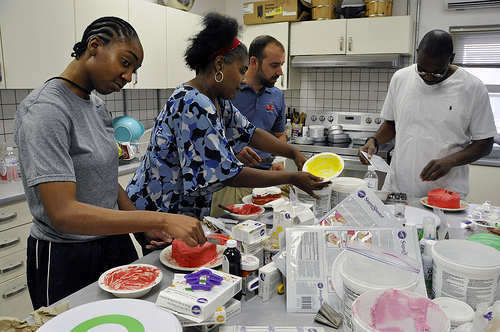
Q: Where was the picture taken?
A: It was taken at the kitchen.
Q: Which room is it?
A: It is a kitchen.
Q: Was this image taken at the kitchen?
A: Yes, it was taken in the kitchen.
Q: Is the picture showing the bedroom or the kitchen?
A: It is showing the kitchen.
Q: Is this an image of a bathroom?
A: No, the picture is showing a kitchen.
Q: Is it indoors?
A: Yes, it is indoors.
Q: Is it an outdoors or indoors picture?
A: It is indoors.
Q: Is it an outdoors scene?
A: No, it is indoors.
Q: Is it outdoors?
A: No, it is indoors.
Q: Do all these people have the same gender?
A: No, they are both male and female.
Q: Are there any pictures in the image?
A: No, there are no pictures.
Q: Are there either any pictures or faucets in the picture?
A: No, there are no pictures or faucets.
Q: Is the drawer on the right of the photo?
A: No, the drawer is on the left of the image.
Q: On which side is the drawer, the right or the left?
A: The drawer is on the left of the image.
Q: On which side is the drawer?
A: The drawer is on the left of the image.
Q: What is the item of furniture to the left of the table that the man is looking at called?
A: The piece of furniture is a drawer.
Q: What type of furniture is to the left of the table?
A: The piece of furniture is a drawer.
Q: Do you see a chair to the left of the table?
A: No, there is a drawer to the left of the table.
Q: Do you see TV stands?
A: No, there are no TV stands.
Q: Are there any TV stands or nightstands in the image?
A: No, there are no TV stands or nightstands.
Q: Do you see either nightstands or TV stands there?
A: No, there are no TV stands or nightstands.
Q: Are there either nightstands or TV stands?
A: No, there are no TV stands or nightstands.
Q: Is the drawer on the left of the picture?
A: Yes, the drawer is on the left of the image.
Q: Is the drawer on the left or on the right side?
A: The drawer is on the left of the image.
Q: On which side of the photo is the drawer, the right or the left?
A: The drawer is on the left of the image.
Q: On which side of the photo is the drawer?
A: The drawer is on the left of the image.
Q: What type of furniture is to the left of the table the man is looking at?
A: The piece of furniture is a drawer.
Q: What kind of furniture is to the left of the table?
A: The piece of furniture is a drawer.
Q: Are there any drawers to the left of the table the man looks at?
A: Yes, there is a drawer to the left of the table.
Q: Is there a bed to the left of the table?
A: No, there is a drawer to the left of the table.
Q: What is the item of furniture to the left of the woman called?
A: The piece of furniture is a drawer.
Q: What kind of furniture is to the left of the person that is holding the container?
A: The piece of furniture is a drawer.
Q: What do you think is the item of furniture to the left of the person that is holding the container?
A: The piece of furniture is a drawer.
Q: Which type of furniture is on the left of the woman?
A: The piece of furniture is a drawer.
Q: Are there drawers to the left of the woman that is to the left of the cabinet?
A: Yes, there is a drawer to the left of the woman.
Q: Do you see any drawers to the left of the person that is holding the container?
A: Yes, there is a drawer to the left of the woman.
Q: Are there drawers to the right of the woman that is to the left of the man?
A: No, the drawer is to the left of the woman.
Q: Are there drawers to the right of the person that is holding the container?
A: No, the drawer is to the left of the woman.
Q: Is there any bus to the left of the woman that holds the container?
A: No, there is a drawer to the left of the woman.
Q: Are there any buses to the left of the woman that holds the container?
A: No, there is a drawer to the left of the woman.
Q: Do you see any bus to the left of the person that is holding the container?
A: No, there is a drawer to the left of the woman.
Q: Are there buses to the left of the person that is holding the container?
A: No, there is a drawer to the left of the woman.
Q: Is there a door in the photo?
A: Yes, there is a door.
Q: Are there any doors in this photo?
A: Yes, there is a door.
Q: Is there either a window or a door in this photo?
A: Yes, there is a door.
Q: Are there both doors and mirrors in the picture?
A: No, there is a door but no mirrors.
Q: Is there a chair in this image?
A: No, there are no chairs.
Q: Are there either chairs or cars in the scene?
A: No, there are no chairs or cars.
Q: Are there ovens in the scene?
A: Yes, there is an oven.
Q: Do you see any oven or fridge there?
A: Yes, there is an oven.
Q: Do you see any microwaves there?
A: No, there are no microwaves.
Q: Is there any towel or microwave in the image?
A: No, there are no microwaves or towels.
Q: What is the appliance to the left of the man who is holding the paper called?
A: The appliance is an oven.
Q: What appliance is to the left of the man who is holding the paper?
A: The appliance is an oven.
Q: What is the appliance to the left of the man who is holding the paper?
A: The appliance is an oven.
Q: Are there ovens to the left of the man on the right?
A: Yes, there is an oven to the left of the man.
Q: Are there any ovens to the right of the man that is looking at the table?
A: No, the oven is to the left of the man.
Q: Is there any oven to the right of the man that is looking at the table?
A: No, the oven is to the left of the man.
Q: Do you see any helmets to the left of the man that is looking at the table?
A: No, there is an oven to the left of the man.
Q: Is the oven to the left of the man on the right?
A: Yes, the oven is to the left of the man.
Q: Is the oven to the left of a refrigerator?
A: No, the oven is to the left of the man.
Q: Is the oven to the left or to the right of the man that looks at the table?
A: The oven is to the left of the man.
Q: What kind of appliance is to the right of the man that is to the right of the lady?
A: The appliance is an oven.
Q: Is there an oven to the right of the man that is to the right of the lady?
A: Yes, there is an oven to the right of the man.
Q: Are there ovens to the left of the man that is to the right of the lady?
A: No, the oven is to the right of the man.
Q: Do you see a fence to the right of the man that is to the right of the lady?
A: No, there is an oven to the right of the man.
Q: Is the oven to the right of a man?
A: Yes, the oven is to the right of a man.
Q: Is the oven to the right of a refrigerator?
A: No, the oven is to the right of a man.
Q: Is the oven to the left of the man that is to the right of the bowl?
A: No, the oven is to the right of the man.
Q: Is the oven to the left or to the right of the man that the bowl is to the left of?
A: The oven is to the right of the man.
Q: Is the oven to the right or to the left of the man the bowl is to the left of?
A: The oven is to the right of the man.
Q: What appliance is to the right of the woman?
A: The appliance is an oven.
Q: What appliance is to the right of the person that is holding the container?
A: The appliance is an oven.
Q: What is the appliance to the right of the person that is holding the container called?
A: The appliance is an oven.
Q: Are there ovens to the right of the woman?
A: Yes, there is an oven to the right of the woman.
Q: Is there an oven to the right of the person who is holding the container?
A: Yes, there is an oven to the right of the woman.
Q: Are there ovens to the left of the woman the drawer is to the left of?
A: No, the oven is to the right of the woman.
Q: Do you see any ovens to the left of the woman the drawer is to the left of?
A: No, the oven is to the right of the woman.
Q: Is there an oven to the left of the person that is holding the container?
A: No, the oven is to the right of the woman.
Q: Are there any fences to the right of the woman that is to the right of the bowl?
A: No, there is an oven to the right of the woman.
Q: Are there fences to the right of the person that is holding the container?
A: No, there is an oven to the right of the woman.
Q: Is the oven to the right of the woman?
A: Yes, the oven is to the right of the woman.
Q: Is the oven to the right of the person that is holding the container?
A: Yes, the oven is to the right of the woman.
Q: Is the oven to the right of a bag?
A: No, the oven is to the right of the woman.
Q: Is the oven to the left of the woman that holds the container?
A: No, the oven is to the right of the woman.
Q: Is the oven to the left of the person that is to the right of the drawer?
A: No, the oven is to the right of the woman.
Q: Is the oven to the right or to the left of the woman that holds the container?
A: The oven is to the right of the woman.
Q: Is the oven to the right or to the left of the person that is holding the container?
A: The oven is to the right of the woman.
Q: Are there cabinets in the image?
A: Yes, there is a cabinet.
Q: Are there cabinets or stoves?
A: Yes, there is a cabinet.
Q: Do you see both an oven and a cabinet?
A: Yes, there are both a cabinet and an oven.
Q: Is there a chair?
A: No, there are no chairs.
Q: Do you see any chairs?
A: No, there are no chairs.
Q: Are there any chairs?
A: No, there are no chairs.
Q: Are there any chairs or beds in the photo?
A: No, there are no chairs or beds.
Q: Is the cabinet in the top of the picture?
A: Yes, the cabinet is in the top of the image.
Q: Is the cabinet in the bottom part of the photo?
A: No, the cabinet is in the top of the image.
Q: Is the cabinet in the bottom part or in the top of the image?
A: The cabinet is in the top of the image.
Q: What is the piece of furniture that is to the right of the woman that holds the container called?
A: The piece of furniture is a cabinet.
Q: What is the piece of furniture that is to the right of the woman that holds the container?
A: The piece of furniture is a cabinet.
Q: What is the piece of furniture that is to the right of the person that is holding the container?
A: The piece of furniture is a cabinet.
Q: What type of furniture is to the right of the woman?
A: The piece of furniture is a cabinet.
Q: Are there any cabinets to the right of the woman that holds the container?
A: Yes, there is a cabinet to the right of the woman.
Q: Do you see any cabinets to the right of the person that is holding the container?
A: Yes, there is a cabinet to the right of the woman.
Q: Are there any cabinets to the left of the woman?
A: No, the cabinet is to the right of the woman.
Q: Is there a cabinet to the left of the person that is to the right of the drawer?
A: No, the cabinet is to the right of the woman.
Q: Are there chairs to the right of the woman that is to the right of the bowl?
A: No, there is a cabinet to the right of the woman.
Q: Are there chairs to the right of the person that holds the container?
A: No, there is a cabinet to the right of the woman.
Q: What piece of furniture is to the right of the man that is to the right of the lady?
A: The piece of furniture is a cabinet.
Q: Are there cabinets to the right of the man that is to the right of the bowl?
A: Yes, there is a cabinet to the right of the man.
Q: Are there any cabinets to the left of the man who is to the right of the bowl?
A: No, the cabinet is to the right of the man.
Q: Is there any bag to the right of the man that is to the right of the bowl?
A: No, there is a cabinet to the right of the man.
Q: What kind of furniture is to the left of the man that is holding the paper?
A: The piece of furniture is a cabinet.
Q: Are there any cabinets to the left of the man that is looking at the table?
A: Yes, there is a cabinet to the left of the man.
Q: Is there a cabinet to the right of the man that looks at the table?
A: No, the cabinet is to the left of the man.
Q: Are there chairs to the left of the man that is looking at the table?
A: No, there is a cabinet to the left of the man.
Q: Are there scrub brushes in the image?
A: No, there are no scrub brushes.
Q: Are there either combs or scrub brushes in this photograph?
A: No, there are no scrub brushes or combs.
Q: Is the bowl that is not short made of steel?
A: No, the bowl is made of plastic.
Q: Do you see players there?
A: No, there are no players.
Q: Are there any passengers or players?
A: No, there are no players or passengers.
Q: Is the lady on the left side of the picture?
A: Yes, the lady is on the left of the image.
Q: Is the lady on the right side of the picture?
A: No, the lady is on the left of the image.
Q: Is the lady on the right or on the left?
A: The lady is on the left of the image.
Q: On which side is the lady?
A: The lady is on the left of the image.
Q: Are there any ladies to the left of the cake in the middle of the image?
A: Yes, there is a lady to the left of the cake.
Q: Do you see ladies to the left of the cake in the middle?
A: Yes, there is a lady to the left of the cake.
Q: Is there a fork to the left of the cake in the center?
A: No, there is a lady to the left of the cake.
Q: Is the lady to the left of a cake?
A: Yes, the lady is to the left of a cake.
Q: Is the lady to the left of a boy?
A: No, the lady is to the left of a cake.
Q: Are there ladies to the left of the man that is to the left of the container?
A: Yes, there is a lady to the left of the man.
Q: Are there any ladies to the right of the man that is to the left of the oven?
A: No, the lady is to the left of the man.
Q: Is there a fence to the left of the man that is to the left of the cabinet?
A: No, there is a lady to the left of the man.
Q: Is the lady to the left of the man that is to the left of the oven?
A: Yes, the lady is to the left of the man.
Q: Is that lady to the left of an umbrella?
A: No, the lady is to the left of the man.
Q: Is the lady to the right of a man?
A: No, the lady is to the left of a man.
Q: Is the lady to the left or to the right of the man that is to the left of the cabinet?
A: The lady is to the left of the man.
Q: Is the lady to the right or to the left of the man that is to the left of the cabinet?
A: The lady is to the left of the man.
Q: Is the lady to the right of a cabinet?
A: No, the lady is to the left of a cabinet.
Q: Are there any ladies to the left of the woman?
A: Yes, there is a lady to the left of the woman.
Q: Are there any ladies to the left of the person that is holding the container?
A: Yes, there is a lady to the left of the woman.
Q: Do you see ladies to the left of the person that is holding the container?
A: Yes, there is a lady to the left of the woman.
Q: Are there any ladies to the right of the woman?
A: No, the lady is to the left of the woman.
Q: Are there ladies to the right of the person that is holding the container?
A: No, the lady is to the left of the woman.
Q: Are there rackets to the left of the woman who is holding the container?
A: No, there is a lady to the left of the woman.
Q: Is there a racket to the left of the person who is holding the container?
A: No, there is a lady to the left of the woman.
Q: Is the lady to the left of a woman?
A: Yes, the lady is to the left of a woman.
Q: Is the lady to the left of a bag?
A: No, the lady is to the left of a woman.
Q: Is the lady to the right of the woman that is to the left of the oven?
A: No, the lady is to the left of the woman.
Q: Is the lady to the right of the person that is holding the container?
A: No, the lady is to the left of the woman.